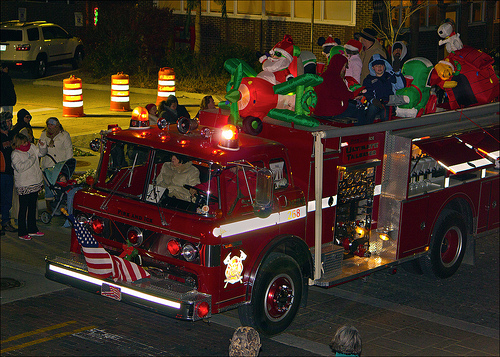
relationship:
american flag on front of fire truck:
[50, 199, 171, 286] [36, 36, 484, 336]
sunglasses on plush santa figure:
[263, 45, 288, 59] [219, 36, 319, 126]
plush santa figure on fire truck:
[219, 36, 319, 126] [34, 45, 490, 352]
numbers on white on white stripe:
[280, 204, 314, 223] [215, 212, 278, 239]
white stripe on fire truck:
[215, 212, 278, 239] [36, 36, 484, 336]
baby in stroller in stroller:
[28, 143, 103, 236] [38, 152, 81, 222]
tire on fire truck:
[255, 248, 306, 329] [34, 45, 490, 352]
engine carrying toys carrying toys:
[204, 18, 497, 126] [248, 11, 467, 126]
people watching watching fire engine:
[13, 118, 95, 253] [47, 81, 483, 335]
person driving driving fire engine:
[150, 153, 228, 226] [54, 84, 496, 352]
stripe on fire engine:
[205, 145, 499, 261] [54, 84, 496, 352]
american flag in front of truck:
[58, 205, 153, 281] [33, 80, 496, 353]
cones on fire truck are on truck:
[38, 66, 189, 124] [33, 80, 496, 353]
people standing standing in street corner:
[1, 107, 76, 242] [1, 89, 103, 312]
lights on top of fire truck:
[121, 95, 268, 170] [34, 89, 490, 352]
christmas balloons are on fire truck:
[207, 41, 500, 129] [34, 89, 490, 352]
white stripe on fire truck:
[204, 136, 496, 254] [34, 89, 490, 352]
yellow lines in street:
[1, 312, 108, 355] [7, 90, 493, 352]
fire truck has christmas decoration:
[34, 89, 490, 352] [203, 19, 492, 136]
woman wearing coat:
[0, 128, 49, 246] [0, 143, 52, 197]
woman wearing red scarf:
[0, 128, 57, 246] [14, 140, 43, 159]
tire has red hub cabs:
[245, 248, 306, 329] [436, 229, 479, 275]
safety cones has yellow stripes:
[20, 314, 95, 350] [8, 308, 100, 351]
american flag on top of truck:
[58, 205, 153, 281] [33, 80, 496, 353]